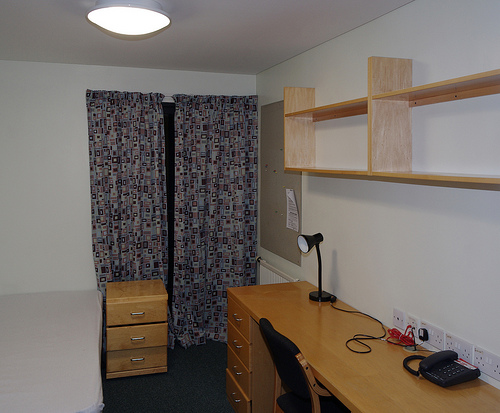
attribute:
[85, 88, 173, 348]
panel — curtain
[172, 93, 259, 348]
curtain — black, white, long, a panel, blue, patterned, closed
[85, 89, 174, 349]
curtain — black, white, long, a panel, blue, patterned, closed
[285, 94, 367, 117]
shelf — empty, wooden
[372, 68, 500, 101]
shelf — empty, wooden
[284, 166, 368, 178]
shelf — empty, wooden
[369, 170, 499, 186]
shelf — empty, wooden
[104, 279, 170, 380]
dresser — brown, small, wooden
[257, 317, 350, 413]
chair — black, brown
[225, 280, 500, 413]
desk — empty, brown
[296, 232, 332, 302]
lamp — black, white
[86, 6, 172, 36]
light — white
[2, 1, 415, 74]
ceiling — white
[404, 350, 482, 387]
telephone — black, corded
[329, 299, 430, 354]
cord — black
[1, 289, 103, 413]
twin bed — unmade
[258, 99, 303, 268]
bulletin board — cork, framed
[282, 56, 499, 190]
shelf set — brown, wooden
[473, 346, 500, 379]
electrical outlet — in row, white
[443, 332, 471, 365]
electrical outlet — in row, white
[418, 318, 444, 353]
electrical outlet — in row, white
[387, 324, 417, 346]
cord — tied, bundled, red, neat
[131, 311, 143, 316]
drawer pull — silver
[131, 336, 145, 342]
drawer pull — silver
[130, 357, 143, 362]
drawer pull — silver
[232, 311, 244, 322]
handle — silver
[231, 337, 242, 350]
handle — silver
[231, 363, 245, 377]
handle — silver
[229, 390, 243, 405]
handle — silver